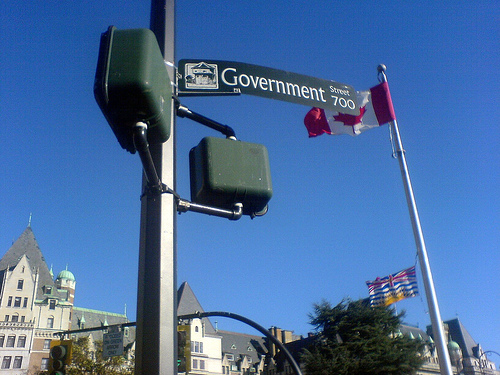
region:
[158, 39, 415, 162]
Sign on the pole.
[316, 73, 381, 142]
Numbers on the sign.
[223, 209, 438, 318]
Flag on the pole.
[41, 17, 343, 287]
Lights on the pole/.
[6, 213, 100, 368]
Buildings in the background.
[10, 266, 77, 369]
Windows on the building.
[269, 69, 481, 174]
Canadian flag on the pole.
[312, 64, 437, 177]
Red and white flag.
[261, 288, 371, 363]
Green leaves on the tree.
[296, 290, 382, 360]
Tree on the street.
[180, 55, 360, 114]
green street sign on pole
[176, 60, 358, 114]
street sign on pole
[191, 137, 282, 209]
back of pedestrian crossing light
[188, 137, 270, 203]
back of green pedestrian crossing light on pole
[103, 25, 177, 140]
back of green pedestrian crossing light on pole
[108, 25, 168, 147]
back of pedestrian crossing light on pole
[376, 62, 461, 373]
flag pole next to street sign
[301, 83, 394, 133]
flag on the pole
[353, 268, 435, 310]
flag on the pole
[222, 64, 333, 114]
words on the street sign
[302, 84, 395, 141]
Canadian Flag flying high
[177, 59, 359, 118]
Street sign on a pole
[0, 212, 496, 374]
Large buildings in the background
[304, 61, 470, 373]
Tall flag pole with two flags flying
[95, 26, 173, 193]
Square shaped street light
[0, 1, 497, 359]
Blue cloudless daytime sky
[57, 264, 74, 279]
Small green dome on roof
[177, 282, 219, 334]
Triangular point in roof on building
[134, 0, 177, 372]
Black metal street pole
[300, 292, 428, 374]
Tree beside flag pole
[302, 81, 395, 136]
Canadian flag on flag pole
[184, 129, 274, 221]
One don't walk sign on post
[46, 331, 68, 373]
Top two lights of a traffic light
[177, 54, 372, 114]
Street sign for Government Street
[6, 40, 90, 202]
Section of blue and cloudless sky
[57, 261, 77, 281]
Green dome on top of building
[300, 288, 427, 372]
Top of green and leafy tree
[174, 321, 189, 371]
Traffic light showing green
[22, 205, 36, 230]
Weather vane on top of pointed roof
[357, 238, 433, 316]
Flag halfway up flag pole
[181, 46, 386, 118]
Sign saids Government Street 700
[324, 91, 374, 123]
Number 700 on the street sign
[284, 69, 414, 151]
Canadian flag on pole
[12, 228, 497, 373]
Large building in background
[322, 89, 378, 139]
Maple leaf on Canadian flag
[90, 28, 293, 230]
Two pedestrian lights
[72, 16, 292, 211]
These boxes are for pedestrians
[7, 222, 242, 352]
Grey pointed roofs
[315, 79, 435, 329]
Two flags on one pole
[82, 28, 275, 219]
Green traffic boxes